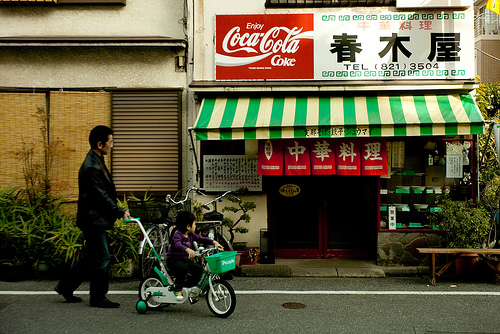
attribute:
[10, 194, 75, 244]
bush — green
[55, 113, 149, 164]
black hair — short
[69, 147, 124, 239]
jacket — black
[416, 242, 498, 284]
bench — wooden, brown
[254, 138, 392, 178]
banners — red, white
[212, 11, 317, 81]
sign — red, white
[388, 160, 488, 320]
bush — large, green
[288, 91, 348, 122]
canopy — green, white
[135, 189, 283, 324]
bike — white, green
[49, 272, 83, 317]
shoe — black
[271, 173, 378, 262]
doorway — brown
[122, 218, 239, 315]
bicycle — green, white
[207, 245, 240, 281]
basket — green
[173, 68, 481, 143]
covering — green, white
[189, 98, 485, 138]
awning — green, white, striped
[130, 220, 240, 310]
bike — green, white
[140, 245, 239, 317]
bike — green, white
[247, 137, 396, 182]
sign — red, hanging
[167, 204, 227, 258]
girl — little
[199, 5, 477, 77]
background — white